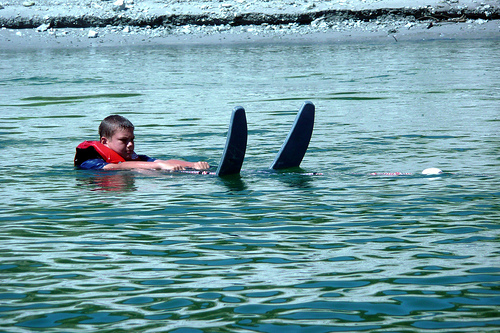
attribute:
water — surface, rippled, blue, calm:
[220, 214, 291, 248]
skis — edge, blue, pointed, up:
[219, 118, 294, 184]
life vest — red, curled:
[103, 150, 119, 158]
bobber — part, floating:
[420, 164, 435, 181]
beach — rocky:
[173, 2, 217, 30]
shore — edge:
[245, 36, 287, 57]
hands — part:
[150, 160, 205, 175]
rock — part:
[286, 23, 308, 36]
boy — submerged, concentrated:
[91, 120, 138, 172]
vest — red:
[78, 146, 99, 171]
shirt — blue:
[129, 158, 137, 162]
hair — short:
[102, 115, 122, 131]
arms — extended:
[136, 154, 198, 172]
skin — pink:
[107, 141, 121, 153]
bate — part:
[151, 154, 182, 172]